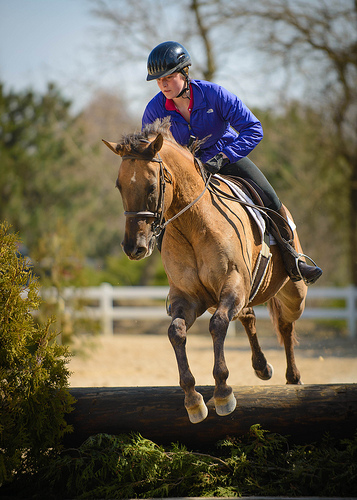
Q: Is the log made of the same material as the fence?
A: Yes, both the log and the fence are made of wood.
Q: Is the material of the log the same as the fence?
A: Yes, both the log and the fence are made of wood.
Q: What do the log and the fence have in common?
A: The material, both the log and the fence are wooden.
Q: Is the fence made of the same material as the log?
A: Yes, both the fence and the log are made of wood.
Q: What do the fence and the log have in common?
A: The material, both the fence and the log are wooden.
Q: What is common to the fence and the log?
A: The material, both the fence and the log are wooden.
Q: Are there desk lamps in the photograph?
A: No, there are no desk lamps.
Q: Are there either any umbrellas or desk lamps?
A: No, there are no desk lamps or umbrellas.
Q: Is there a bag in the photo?
A: No, there are no bags.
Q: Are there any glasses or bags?
A: No, there are no bags or glasses.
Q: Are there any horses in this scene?
A: Yes, there is a horse.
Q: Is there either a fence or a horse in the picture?
A: Yes, there is a horse.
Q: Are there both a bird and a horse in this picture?
A: No, there is a horse but no birds.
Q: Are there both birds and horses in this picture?
A: No, there is a horse but no birds.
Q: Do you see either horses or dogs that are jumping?
A: Yes, the horse is jumping.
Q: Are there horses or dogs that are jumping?
A: Yes, the horse is jumping.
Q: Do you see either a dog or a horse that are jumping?
A: Yes, the horse is jumping.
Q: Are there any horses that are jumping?
A: Yes, there is a horse that is jumping.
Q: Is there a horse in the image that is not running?
A: Yes, there is a horse that is jumping.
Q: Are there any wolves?
A: No, there are no wolves.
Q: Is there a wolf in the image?
A: No, there are no wolves.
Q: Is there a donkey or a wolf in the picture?
A: No, there are no wolves or donkeys.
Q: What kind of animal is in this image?
A: The animal is a horse.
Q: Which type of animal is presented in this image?
A: The animal is a horse.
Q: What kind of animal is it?
A: The animal is a horse.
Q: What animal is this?
A: This is a horse.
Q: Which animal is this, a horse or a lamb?
A: This is a horse.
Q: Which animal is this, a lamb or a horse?
A: This is a horse.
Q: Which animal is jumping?
A: The animal is a horse.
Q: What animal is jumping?
A: The animal is a horse.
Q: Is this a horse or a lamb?
A: This is a horse.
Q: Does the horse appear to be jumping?
A: Yes, the horse is jumping.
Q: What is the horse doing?
A: The horse is jumping.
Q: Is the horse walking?
A: No, the horse is jumping.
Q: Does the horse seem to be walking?
A: No, the horse is jumping.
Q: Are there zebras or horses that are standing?
A: No, there is a horse but it is jumping.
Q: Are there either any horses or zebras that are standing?
A: No, there is a horse but it is jumping.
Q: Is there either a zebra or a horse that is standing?
A: No, there is a horse but it is jumping.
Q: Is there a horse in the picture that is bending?
A: No, there is a horse but it is jumping.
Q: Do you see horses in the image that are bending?
A: No, there is a horse but it is jumping.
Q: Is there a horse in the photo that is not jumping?
A: No, there is a horse but it is jumping.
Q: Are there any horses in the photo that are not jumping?
A: No, there is a horse but it is jumping.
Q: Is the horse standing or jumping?
A: The horse is jumping.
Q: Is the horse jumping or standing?
A: The horse is jumping.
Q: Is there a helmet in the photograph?
A: Yes, there is a helmet.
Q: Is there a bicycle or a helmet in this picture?
A: Yes, there is a helmet.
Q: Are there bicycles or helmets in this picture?
A: Yes, there is a helmet.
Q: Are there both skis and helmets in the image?
A: No, there is a helmet but no skis.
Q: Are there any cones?
A: No, there are no cones.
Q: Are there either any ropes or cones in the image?
A: No, there are no cones or ropes.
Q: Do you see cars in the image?
A: No, there are no cars.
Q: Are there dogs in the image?
A: No, there are no dogs.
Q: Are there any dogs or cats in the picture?
A: No, there are no dogs or cats.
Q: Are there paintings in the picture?
A: No, there are no paintings.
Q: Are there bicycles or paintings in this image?
A: No, there are no paintings or bicycles.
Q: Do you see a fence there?
A: Yes, there is a fence.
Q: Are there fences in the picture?
A: Yes, there is a fence.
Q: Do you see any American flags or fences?
A: Yes, there is a fence.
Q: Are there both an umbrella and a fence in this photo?
A: No, there is a fence but no umbrellas.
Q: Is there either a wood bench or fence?
A: Yes, there is a wood fence.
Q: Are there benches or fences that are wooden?
A: Yes, the fence is wooden.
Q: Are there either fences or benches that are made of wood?
A: Yes, the fence is made of wood.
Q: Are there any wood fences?
A: Yes, there is a wood fence.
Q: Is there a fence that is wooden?
A: Yes, there is a fence that is wooden.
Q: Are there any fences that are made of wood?
A: Yes, there is a fence that is made of wood.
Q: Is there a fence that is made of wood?
A: Yes, there is a fence that is made of wood.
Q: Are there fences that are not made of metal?
A: Yes, there is a fence that is made of wood.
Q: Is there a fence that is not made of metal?
A: Yes, there is a fence that is made of wood.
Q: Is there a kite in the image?
A: No, there are no kites.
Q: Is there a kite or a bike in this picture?
A: No, there are no kites or bikes.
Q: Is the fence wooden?
A: Yes, the fence is wooden.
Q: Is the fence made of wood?
A: Yes, the fence is made of wood.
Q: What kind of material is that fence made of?
A: The fence is made of wood.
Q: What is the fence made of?
A: The fence is made of wood.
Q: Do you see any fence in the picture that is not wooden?
A: No, there is a fence but it is wooden.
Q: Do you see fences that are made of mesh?
A: No, there is a fence but it is made of wood.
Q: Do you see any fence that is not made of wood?
A: No, there is a fence but it is made of wood.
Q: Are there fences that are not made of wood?
A: No, there is a fence but it is made of wood.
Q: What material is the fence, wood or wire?
A: The fence is made of wood.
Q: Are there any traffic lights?
A: No, there are no traffic lights.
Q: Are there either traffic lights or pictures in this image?
A: No, there are no traffic lights or pictures.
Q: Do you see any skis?
A: No, there are no skis.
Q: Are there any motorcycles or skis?
A: No, there are no skis or motorcycles.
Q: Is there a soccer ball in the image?
A: No, there are no soccer balls.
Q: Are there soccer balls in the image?
A: No, there are no soccer balls.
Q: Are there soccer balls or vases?
A: No, there are no soccer balls or vases.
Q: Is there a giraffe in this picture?
A: No, there are no giraffes.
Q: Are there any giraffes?
A: No, there are no giraffes.